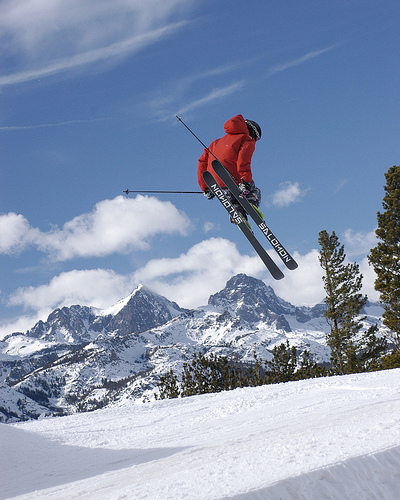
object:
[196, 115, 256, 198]
coat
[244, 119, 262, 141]
head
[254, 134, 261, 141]
goggles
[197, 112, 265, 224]
man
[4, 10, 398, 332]
air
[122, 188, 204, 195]
pole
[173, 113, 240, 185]
pole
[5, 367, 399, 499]
snow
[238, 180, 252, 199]
hand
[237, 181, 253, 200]
glove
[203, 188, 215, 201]
glove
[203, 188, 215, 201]
hand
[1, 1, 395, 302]
blue sky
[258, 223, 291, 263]
word salomon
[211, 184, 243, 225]
writing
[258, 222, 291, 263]
writing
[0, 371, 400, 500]
ski tracks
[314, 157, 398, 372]
trees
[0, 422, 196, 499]
shadow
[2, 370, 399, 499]
ski hill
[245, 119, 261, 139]
hat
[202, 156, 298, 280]
person's ski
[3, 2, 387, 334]
sky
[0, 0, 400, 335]
cloud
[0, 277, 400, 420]
hill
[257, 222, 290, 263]
label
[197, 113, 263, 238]
jump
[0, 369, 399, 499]
ground